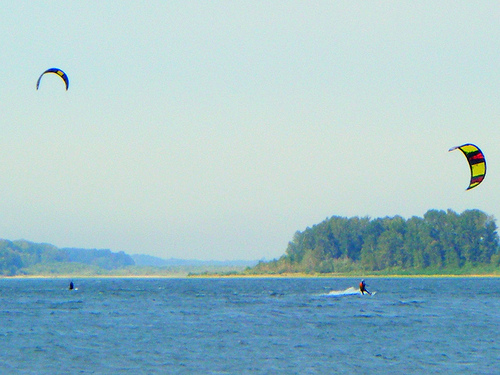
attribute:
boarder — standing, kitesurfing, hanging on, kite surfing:
[69, 281, 74, 290]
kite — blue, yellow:
[35, 68, 69, 91]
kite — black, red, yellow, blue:
[448, 143, 488, 192]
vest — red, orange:
[359, 282, 364, 288]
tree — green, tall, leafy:
[454, 210, 486, 240]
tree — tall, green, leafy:
[359, 236, 378, 271]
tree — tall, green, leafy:
[375, 230, 402, 270]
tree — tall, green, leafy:
[286, 230, 303, 263]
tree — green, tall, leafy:
[479, 220, 499, 243]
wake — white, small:
[326, 286, 368, 295]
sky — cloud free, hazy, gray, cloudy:
[1, 1, 500, 261]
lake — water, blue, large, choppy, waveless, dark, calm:
[0, 276, 499, 374]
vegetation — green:
[188, 208, 499, 276]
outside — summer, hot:
[0, 1, 499, 374]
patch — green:
[286, 208, 500, 276]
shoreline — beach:
[0, 273, 498, 280]